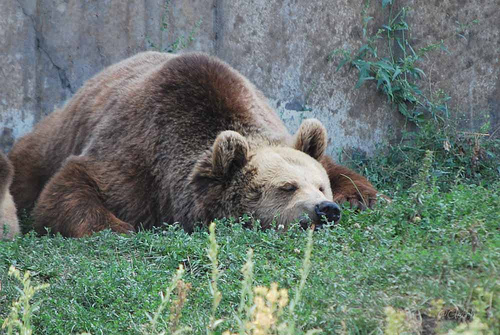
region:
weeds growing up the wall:
[328, 16, 495, 177]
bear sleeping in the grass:
[21, 26, 381, 259]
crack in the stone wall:
[23, 22, 73, 86]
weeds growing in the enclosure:
[136, 243, 327, 333]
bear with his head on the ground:
[219, 120, 359, 227]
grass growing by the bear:
[59, 248, 145, 297]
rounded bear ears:
[288, 108, 325, 165]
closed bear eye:
[274, 178, 299, 198]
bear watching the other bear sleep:
[2, 136, 35, 326]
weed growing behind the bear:
[140, 8, 201, 58]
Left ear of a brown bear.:
[209, 125, 245, 177]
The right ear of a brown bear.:
[292, 113, 326, 163]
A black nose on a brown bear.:
[312, 195, 337, 220]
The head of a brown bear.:
[202, 121, 342, 226]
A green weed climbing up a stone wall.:
[337, 4, 482, 137]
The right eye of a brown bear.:
[275, 174, 297, 195]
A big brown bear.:
[0, 44, 388, 229]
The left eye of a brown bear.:
[315, 183, 332, 198]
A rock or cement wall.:
[0, 0, 497, 155]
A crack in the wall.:
[13, 4, 73, 96]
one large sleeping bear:
[23, 48, 394, 240]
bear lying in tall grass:
[22, 27, 401, 318]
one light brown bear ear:
[197, 130, 250, 180]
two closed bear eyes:
[269, 173, 328, 195]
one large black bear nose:
[314, 200, 345, 222]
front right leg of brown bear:
[29, 151, 141, 236]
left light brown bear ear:
[293, 114, 331, 168]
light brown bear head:
[232, 147, 344, 226]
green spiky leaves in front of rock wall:
[331, 3, 458, 141]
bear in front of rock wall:
[13, 20, 428, 224]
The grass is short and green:
[85, 241, 371, 311]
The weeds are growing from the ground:
[128, 265, 346, 330]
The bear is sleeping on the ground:
[5, 17, 372, 248]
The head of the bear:
[208, 116, 345, 237]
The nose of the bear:
[311, 191, 347, 224]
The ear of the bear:
[199, 127, 251, 177]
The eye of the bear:
[266, 166, 299, 200]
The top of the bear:
[145, 45, 385, 260]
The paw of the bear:
[333, 159, 394, 218]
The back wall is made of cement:
[265, 18, 402, 108]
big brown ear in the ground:
[5, 49, 369, 231]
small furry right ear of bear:
[210, 132, 245, 174]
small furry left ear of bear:
[291, 119, 329, 160]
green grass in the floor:
[4, 138, 489, 332]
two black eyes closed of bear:
[277, 182, 331, 199]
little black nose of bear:
[312, 203, 339, 220]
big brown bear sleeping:
[7, 46, 392, 228]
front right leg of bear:
[25, 155, 133, 239]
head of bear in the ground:
[205, 118, 335, 226]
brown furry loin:
[98, 46, 262, 126]